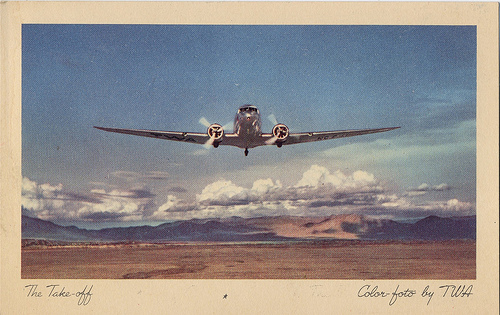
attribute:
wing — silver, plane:
[260, 118, 402, 150]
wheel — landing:
[236, 146, 252, 161]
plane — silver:
[94, 104, 399, 159]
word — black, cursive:
[346, 278, 397, 305]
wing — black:
[154, 131, 199, 145]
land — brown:
[20, 245, 475, 283]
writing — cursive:
[19, 279, 101, 314]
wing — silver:
[75, 116, 239, 161]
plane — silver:
[93, 98, 406, 146]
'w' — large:
[167, 132, 180, 144]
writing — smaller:
[303, 136, 361, 141]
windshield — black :
[239, 106, 256, 115]